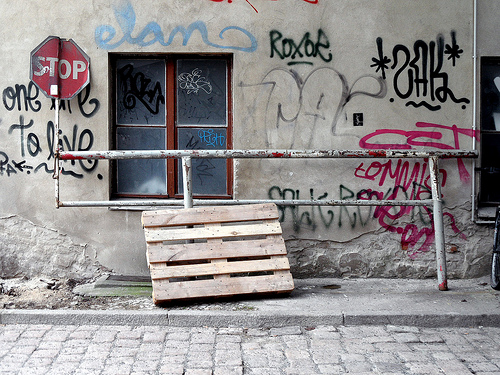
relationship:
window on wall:
[110, 54, 235, 201] [1, 1, 496, 277]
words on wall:
[2, 1, 476, 256] [1, 1, 496, 277]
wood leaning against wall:
[139, 202, 293, 301] [1, 1, 496, 277]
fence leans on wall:
[55, 150, 479, 289] [1, 1, 496, 277]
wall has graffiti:
[1, 1, 496, 277] [2, 1, 476, 256]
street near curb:
[1, 325, 496, 374] [1, 312, 499, 324]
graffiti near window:
[2, 1, 476, 256] [110, 54, 235, 201]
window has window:
[110, 54, 235, 201] [110, 54, 235, 201]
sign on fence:
[30, 35, 91, 99] [55, 150, 479, 289]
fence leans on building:
[55, 150, 479, 289] [1, 1, 496, 277]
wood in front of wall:
[139, 202, 293, 301] [1, 1, 496, 277]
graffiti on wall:
[2, 1, 476, 256] [1, 1, 496, 277]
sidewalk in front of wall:
[1, 278, 497, 315] [1, 1, 496, 277]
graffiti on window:
[2, 1, 476, 256] [110, 54, 235, 201]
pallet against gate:
[142, 204, 293, 301] [55, 149, 478, 292]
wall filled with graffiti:
[1, 1, 496, 277] [2, 1, 476, 256]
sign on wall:
[30, 35, 91, 99] [1, 1, 496, 277]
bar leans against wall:
[55, 150, 478, 159] [1, 1, 496, 277]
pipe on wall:
[472, 1, 477, 225] [1, 1, 496, 277]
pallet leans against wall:
[142, 204, 293, 301] [1, 1, 496, 277]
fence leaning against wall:
[55, 150, 479, 289] [1, 1, 496, 277]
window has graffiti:
[110, 54, 235, 201] [122, 67, 223, 150]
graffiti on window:
[122, 67, 223, 150] [110, 54, 235, 201]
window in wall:
[110, 54, 235, 201] [1, 1, 496, 277]